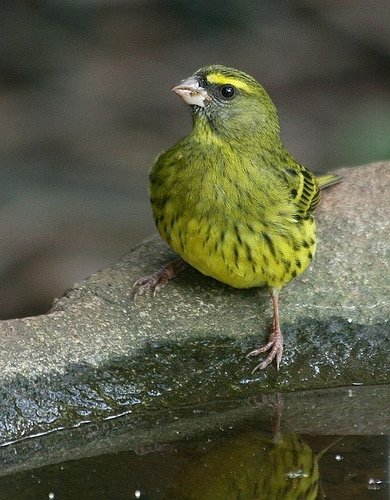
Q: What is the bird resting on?
A: Rock.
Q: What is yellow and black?
A: Bird.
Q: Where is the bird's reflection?
A: Water.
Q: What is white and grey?
A: Beak.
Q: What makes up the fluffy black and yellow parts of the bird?
A: Feathers.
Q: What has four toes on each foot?
A: Bird.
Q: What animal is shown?
A: A bird.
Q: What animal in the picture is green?
A: A bird.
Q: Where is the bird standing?
A: On a rock.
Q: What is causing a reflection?
A: Water.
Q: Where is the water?
A: In front of the bird.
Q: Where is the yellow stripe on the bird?
A: Over it's eye.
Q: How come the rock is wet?
A: It's touching water.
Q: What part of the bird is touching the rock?
A: It's feet.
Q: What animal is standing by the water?
A: A bird.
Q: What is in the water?
A: Birds reflection.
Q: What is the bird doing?
A: Sticking 1 foot out.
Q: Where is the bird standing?
A: On a bird bath.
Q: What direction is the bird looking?
A: Left.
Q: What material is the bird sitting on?
A: Cement.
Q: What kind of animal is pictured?
A: A bird.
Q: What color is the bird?
A: Yellowish.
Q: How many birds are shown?
A: 1.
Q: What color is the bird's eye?
A: Black.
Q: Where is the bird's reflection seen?
A: In the water.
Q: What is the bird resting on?
A: Concrete.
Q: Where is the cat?
A: There isn't one.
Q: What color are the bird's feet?
A: Brown.